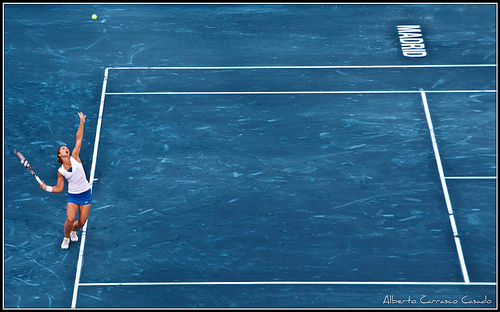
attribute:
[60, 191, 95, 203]
skirt — blue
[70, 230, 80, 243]
sneaker — white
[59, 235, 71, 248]
sneaker — white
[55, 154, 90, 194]
top — white, tank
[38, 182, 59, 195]
wristband — white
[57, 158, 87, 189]
top — white, tank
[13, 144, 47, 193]
racket — tennis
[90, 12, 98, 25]
ball — green, tennis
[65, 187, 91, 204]
shorts — dark blue, blue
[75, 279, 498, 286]
white line — long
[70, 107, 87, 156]
arm — fully outstretched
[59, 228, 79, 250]
shoes — white, tennis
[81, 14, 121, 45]
ball — green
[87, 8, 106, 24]
ball — tennis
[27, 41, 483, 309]
court — tennis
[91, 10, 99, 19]
ball — green